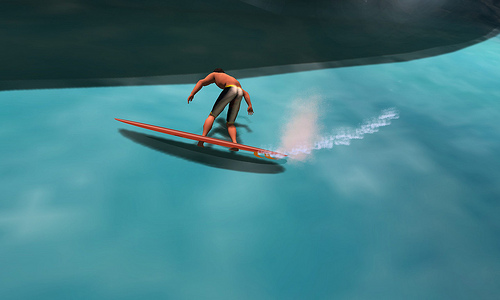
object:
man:
[188, 67, 255, 152]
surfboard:
[114, 118, 288, 159]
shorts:
[209, 85, 244, 125]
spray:
[258, 106, 400, 159]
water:
[0, 162, 500, 298]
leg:
[202, 114, 215, 140]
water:
[0, 0, 496, 59]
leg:
[228, 124, 237, 145]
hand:
[247, 106, 254, 115]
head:
[213, 67, 225, 73]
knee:
[208, 114, 216, 124]